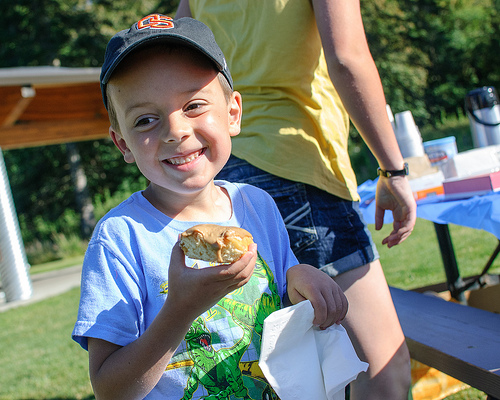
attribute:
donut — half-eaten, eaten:
[180, 226, 253, 263]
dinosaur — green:
[182, 316, 253, 396]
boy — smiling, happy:
[72, 15, 347, 399]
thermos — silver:
[461, 86, 499, 147]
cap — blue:
[99, 14, 234, 110]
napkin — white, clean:
[256, 299, 372, 398]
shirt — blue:
[70, 180, 301, 400]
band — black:
[373, 167, 406, 178]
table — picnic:
[341, 168, 498, 399]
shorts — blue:
[213, 148, 380, 277]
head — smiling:
[102, 12, 242, 192]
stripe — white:
[284, 200, 309, 224]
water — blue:
[355, 174, 380, 199]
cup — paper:
[392, 109, 419, 143]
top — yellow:
[188, 1, 363, 200]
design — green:
[162, 252, 282, 399]